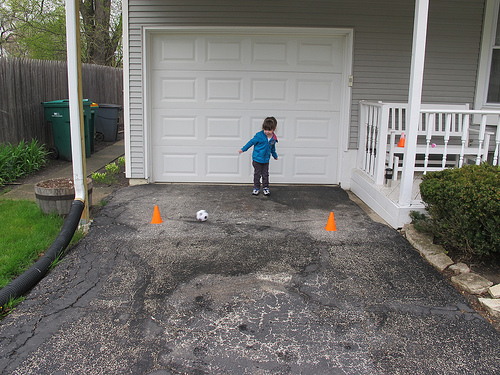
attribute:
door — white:
[144, 23, 358, 190]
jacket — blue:
[240, 129, 276, 166]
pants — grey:
[251, 161, 268, 192]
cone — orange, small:
[389, 126, 421, 167]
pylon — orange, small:
[320, 211, 337, 236]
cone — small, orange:
[395, 129, 407, 150]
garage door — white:
[145, 27, 348, 181]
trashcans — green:
[35, 96, 96, 156]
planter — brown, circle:
[31, 171, 96, 215]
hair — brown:
[262, 112, 281, 134]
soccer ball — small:
[194, 209, 208, 223]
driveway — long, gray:
[2, 180, 497, 370]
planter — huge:
[33, 176, 91, 216]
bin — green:
[41, 99, 91, 157]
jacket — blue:
[239, 136, 282, 171]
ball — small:
[188, 208, 215, 225]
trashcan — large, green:
[42, 95, 96, 163]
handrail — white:
[359, 93, 495, 163]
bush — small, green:
[409, 159, 499, 266]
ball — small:
[193, 204, 213, 227]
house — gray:
[61, 0, 484, 244]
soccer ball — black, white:
[193, 206, 209, 224]